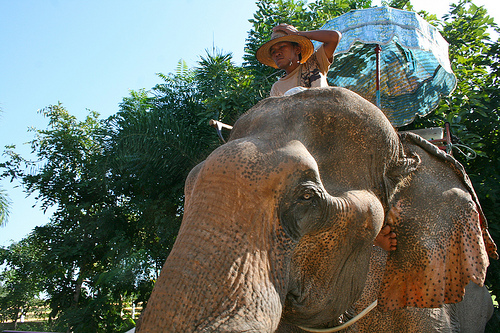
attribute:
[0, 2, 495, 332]
tree — green, leafy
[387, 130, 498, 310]
ear — big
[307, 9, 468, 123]
umbrella — blue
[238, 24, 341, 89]
man — asian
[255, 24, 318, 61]
hat — straw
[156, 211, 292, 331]
trunk — orange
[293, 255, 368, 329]
skin — sagging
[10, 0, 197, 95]
blue sky — clear, in the background 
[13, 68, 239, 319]
tree leaves — green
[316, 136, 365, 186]
skin — gray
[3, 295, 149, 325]
fence — white, wooden